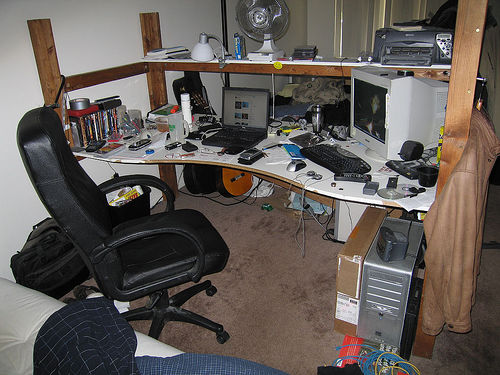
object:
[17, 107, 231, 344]
chair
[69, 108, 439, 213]
desk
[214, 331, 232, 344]
wheels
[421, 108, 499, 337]
brown jacket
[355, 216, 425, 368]
computer tower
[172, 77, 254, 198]
guitar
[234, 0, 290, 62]
fan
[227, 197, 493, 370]
carpet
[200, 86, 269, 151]
laptop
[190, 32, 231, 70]
white lamp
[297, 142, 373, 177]
keyboard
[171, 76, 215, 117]
black phone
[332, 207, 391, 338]
cardboard box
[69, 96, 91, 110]
duct tape roll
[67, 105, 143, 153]
dvds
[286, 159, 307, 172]
mouse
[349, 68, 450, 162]
monitor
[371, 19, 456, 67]
printer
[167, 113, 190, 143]
white plastic cup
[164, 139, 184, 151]
cell phone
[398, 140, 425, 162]
speaker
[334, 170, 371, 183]
black remote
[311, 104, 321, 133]
silver travel mug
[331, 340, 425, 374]
blue cords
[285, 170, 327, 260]
gray cords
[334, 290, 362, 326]
white label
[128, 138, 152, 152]
sony psp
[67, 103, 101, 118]
red book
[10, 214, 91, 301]
black bag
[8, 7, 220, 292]
wall